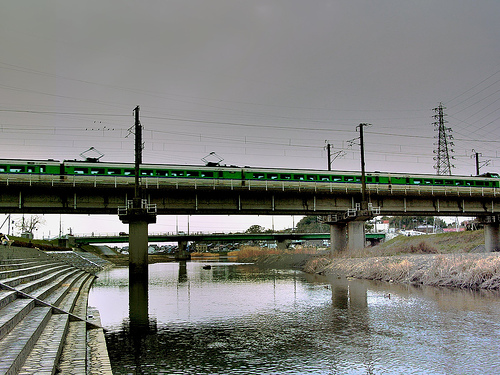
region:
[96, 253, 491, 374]
shallow body of water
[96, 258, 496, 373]
narrow body of water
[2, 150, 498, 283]
bridge over the water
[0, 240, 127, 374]
steps leading down to the water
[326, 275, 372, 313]
reflection in the water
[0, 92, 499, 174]
power lines running along the bridge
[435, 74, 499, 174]
thin wires running parallel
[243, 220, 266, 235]
top of a tree visible over the bridge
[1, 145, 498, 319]
two bridges over water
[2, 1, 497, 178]
the sky is dark gray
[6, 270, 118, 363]
these are stone steps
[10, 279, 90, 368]
the steps lead to the river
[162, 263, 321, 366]
the river is calm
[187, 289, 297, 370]
the river water is green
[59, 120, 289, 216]
this is a train bridge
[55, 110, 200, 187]
the train is electric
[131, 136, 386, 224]
this is a train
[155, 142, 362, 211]
this is a passenger train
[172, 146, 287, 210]
the train is green and white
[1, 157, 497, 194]
a long green train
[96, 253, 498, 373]
a dark rippling river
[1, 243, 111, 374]
concrete steps along a river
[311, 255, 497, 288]
brown grass along a riverbank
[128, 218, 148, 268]
concrete pillars under a bridge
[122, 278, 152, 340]
the reflection of a pillar in the water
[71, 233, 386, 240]
a long green bridge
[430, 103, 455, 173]
a tall gray metal tower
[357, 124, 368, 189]
black metal light pole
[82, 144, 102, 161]
a metal diamond shape on a track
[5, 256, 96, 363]
a concrete structure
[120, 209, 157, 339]
a concrete column of the bridge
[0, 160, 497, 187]
a long green train crossing the bridge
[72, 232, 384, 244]
another bridge on the scene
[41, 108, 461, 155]
the train electrical wirings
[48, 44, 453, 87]
a gray sky on the background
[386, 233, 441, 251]
some grass in this area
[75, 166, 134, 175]
the train passengers window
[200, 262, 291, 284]
reflection of the area on the water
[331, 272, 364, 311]
the reflection of the colummns on the water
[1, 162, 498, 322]
Two bridges are over a river.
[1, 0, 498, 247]
The sky is gray.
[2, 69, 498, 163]
Wires are attached to the poles.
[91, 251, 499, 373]
Water has reflections on it.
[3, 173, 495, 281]
The bridges are supportedby piers.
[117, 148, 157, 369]
A pier is reflected in water.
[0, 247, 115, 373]
Steps are by a body of water.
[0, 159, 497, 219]
A green and white train is on a bridge.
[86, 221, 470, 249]
Buildings are behind a green bridge.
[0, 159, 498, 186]
A green andwhite train has mostly rectangular windows.